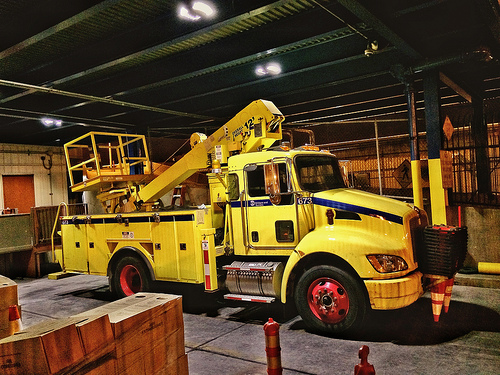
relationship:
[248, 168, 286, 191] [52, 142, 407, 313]
window of truck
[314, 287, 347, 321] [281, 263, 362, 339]
rim of tire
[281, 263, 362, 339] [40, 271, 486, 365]
tire in ground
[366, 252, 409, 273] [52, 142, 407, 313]
headlights on truck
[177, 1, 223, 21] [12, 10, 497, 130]
light on roof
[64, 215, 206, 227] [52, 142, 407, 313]
stripe of truck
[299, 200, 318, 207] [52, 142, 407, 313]
number on truck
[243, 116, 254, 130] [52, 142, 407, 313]
number on truck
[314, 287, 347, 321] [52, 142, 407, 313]
rim of truck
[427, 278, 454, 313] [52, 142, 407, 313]
cones on truck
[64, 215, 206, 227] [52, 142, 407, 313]
stripe on truck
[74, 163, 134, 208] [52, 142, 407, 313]
bucket on truck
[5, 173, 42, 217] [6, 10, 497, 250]
door in building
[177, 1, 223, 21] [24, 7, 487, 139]
light on ceiling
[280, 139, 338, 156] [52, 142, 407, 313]
lights on truck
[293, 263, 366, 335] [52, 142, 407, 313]
tire on truck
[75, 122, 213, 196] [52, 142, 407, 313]
lift on truck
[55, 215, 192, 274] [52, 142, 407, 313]
compartments on truck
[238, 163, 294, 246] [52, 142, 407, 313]
door of truck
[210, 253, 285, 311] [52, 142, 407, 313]
steps on truck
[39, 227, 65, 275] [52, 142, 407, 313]
step on truck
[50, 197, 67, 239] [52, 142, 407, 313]
rail on truck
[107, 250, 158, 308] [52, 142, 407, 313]
tire of truck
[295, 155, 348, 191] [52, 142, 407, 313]
windshield of truck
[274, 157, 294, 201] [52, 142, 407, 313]
mirror of truck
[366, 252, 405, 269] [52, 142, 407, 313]
headlights of truck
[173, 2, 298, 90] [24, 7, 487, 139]
lights above ceiling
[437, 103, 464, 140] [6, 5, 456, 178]
sign in background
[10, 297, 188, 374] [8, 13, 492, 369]
crates in warehouse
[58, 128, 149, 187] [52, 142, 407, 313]
cage on truck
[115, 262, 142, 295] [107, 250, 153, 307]
hub cap on tire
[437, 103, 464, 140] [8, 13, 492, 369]
sign in warehouse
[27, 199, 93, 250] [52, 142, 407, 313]
fence behind truck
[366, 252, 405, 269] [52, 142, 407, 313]
headlights on truck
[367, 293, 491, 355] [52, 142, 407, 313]
shadow of truck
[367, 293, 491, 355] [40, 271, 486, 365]
shadow on ground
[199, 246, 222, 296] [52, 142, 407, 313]
reflectors on truck